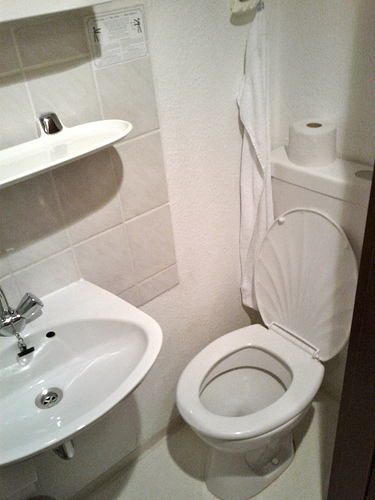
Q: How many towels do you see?
A: 1.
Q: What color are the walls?
A: White.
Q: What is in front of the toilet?
A: A Sink.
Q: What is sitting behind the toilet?
A: Roll of toilet paper.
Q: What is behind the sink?
A: Tile.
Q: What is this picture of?
A: A Bathroom.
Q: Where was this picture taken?
A: In a bathroom.